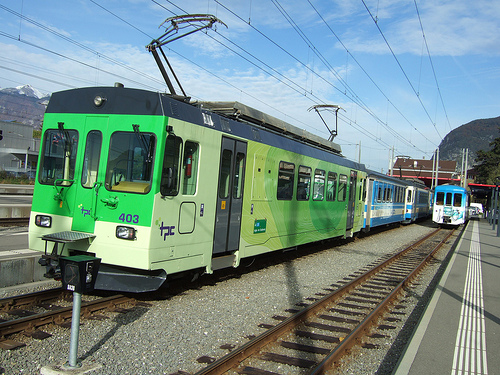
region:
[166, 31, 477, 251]
the sky is cloudy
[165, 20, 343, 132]
the sky is cloudy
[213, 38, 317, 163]
the sky is cloudy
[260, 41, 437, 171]
the sky is cloudy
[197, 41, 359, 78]
the sky is cloudy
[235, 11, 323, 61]
the sky is cloudy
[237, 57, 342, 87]
the sky is cloudy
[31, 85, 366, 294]
green car on train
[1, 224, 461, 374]
sets of rail road tracks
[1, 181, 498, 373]
train platforms made of concrete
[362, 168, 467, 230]
train cars are blue and white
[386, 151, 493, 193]
train station roof in background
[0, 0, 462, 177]
power lines hang above trains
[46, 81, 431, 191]
black top on train cars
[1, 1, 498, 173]
blue sky with clouds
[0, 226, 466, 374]
Tracks surrounded by gravel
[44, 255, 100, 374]
train signal box is black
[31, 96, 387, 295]
commuter train on track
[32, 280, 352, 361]
two sets on train tracks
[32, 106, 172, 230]
green front of train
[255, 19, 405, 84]
wires above train tracks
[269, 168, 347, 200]
windows on side of train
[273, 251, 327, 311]
shadow on gray gravel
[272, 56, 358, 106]
white clouds in daytime sky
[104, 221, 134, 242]
light on front of train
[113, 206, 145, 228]
blue letters on train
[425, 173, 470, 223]
train with blue top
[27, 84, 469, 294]
two trains on the railroad tracks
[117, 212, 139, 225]
number 403 on the front of the train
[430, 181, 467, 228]
blue and white train on the tracks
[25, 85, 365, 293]
a blue and black train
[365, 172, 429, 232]
a blue and white train car behind the green train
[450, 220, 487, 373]
safety white lines on the pedestrian walkway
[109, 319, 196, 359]
grey gravels between the railroad tracks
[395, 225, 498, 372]
grey and white pedestrian walkway beside the tracks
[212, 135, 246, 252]
dark grey doors on the side of the green train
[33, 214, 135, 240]
two headlights on the front of the green train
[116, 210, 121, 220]
The number 4 on the front of the trolley.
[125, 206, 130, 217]
The 0 on the front of the trolley.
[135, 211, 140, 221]
The number 3 on the front of the trolley.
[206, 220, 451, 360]
The tracks to the right of the green trolley.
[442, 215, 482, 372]
The white lines on the platform on the right.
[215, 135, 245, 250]
The first set of doors on the green trolley.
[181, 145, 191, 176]
The red fire extinguisher inside of the green trolley.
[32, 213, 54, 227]
The left headlight on the green trolley.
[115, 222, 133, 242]
The right headlight on the green trolley.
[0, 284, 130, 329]
The tracks in front of the green trolley.